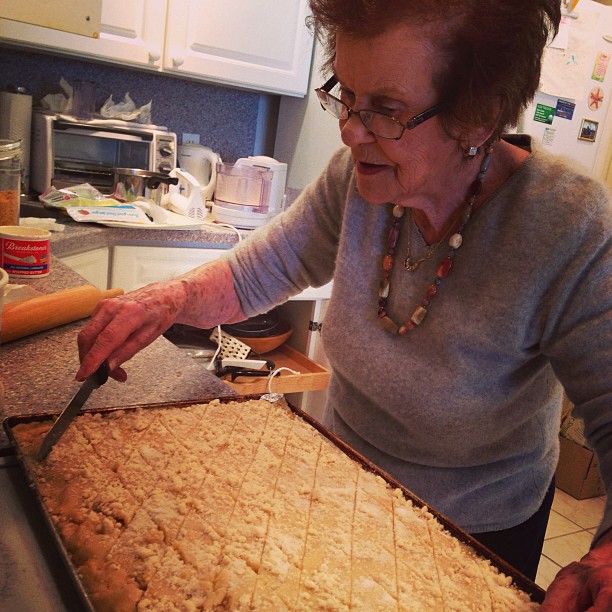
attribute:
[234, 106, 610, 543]
shirt — long sleeve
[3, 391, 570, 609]
tray — baked goods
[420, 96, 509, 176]
earring — square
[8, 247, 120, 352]
pin — brown and wooden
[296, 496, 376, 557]
flaky pastry — a peice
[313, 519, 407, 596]
flaky pastry — a peice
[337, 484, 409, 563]
flaky pastry — a peice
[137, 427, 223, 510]
flaky pastry — a peice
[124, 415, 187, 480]
flaky pastry — a peice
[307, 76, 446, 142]
glasses — black framed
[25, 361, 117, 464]
knife — blank handled, silver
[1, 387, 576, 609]
pan — brown and silver, rectangle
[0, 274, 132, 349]
rolling pin — brown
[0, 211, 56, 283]
containerr — mostly red, round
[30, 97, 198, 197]
toaster oven — white and silver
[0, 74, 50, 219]
paper towels — white roll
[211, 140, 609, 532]
shirt — gray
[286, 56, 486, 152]
eyeglasses — dark pair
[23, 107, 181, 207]
microwave oven — white and silver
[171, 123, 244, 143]
doors — white